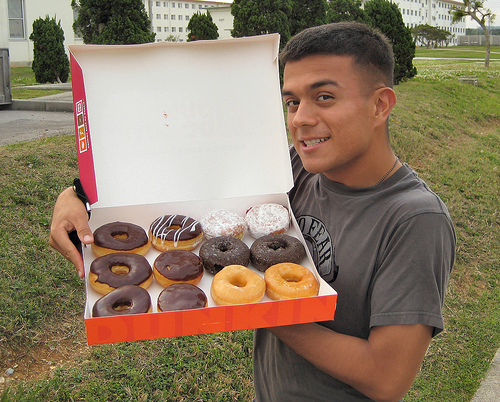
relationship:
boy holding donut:
[59, 43, 428, 370] [89, 283, 152, 316]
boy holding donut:
[59, 43, 428, 370] [87, 250, 152, 296]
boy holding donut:
[59, 43, 428, 370] [90, 214, 150, 257]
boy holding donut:
[59, 43, 428, 370] [207, 261, 267, 304]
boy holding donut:
[59, 43, 428, 370] [150, 243, 205, 284]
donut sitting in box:
[89, 218, 152, 256] [64, 33, 338, 350]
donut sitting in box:
[148, 210, 203, 250] [64, 33, 338, 350]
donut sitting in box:
[199, 208, 246, 238] [64, 33, 338, 350]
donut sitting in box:
[262, 260, 319, 298] [64, 33, 338, 350]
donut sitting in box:
[209, 263, 266, 306] [64, 33, 338, 350]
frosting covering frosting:
[150, 212, 203, 241] [150, 212, 199, 248]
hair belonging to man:
[272, 19, 394, 93] [277, 17, 407, 172]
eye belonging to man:
[312, 90, 335, 103] [282, 23, 477, 279]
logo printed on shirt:
[295, 211, 341, 286] [249, 140, 457, 400]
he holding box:
[245, 18, 487, 316] [64, 33, 338, 350]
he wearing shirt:
[252, 21, 457, 402] [261, 177, 451, 399]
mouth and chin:
[293, 130, 329, 152] [297, 158, 337, 173]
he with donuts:
[252, 21, 457, 402] [92, 190, 273, 300]